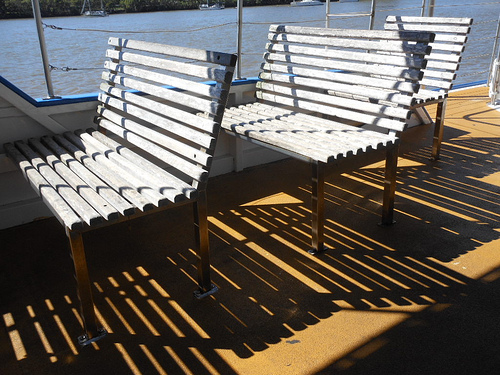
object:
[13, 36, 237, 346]
bench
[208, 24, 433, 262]
bench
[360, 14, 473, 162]
bench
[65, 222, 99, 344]
leg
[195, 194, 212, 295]
leg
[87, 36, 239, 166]
bench back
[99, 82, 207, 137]
slat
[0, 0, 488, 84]
body of water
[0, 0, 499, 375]
boat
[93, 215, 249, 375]
shadow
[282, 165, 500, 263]
shadow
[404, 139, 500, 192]
shadow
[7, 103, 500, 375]
deck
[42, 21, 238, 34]
safety wire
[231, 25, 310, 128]
shadow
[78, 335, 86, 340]
bolt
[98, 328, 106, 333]
bolt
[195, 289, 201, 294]
bolt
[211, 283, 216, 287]
bolt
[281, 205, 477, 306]
shadow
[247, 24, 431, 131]
bench back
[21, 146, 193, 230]
seat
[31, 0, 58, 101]
pole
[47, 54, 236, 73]
safety wire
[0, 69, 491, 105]
edge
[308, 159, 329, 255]
leg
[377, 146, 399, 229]
leg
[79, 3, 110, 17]
sailboat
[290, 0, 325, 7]
boat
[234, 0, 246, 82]
pole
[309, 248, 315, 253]
bolt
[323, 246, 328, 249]
bolt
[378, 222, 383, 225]
bolt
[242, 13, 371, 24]
safety wire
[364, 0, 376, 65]
pole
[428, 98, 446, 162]
leg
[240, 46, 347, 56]
safety wire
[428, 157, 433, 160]
bolt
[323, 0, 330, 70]
pole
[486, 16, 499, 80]
pole